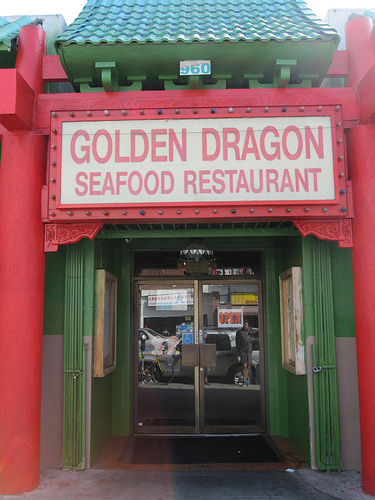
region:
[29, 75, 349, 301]
an Asian restaurant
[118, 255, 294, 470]
the entrance way to the restaurant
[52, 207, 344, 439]
the entrance way has green trim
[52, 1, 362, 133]
the top part of the eatery is green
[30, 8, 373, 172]
this roof has an Far Eastern design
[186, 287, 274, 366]
this restaurant is open for business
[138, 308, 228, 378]
this diner is handicap accessible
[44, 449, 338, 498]
the ground beneath the door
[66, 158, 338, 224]
this diner specializes in seafood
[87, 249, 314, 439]
there are two pictures at the entrance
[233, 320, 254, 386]
a reflection of a man standing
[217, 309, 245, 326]
a red and white open sign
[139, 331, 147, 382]
a black and gray parking meter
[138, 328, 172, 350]
part of a car in a window reflection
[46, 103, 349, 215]
a red and white restaurant sign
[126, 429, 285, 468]
a black door mat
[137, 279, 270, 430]
the doors of a restaurant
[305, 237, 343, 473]
part of a green door frame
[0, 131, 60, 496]
a large red pole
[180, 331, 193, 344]
a blue and white handicapped sign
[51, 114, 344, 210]
sign for the restaurant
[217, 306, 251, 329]
sign indicating they are open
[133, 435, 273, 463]
mat to wipe your feet on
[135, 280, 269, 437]
doors for the restaurant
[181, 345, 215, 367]
things to pull open the doors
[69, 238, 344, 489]
gates they close when restaurant closes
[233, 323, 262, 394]
man's reflection taking picture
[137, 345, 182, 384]
reflection of man's bike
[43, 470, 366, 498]
side walk leading to restaurant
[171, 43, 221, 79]
address of restaurant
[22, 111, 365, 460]
The Golden Dragon seafood restaurant entry way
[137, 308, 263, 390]
Reflection of the people and cars across from the restaurant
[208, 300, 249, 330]
Sign indicating the restaurant is open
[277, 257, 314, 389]
Enclosed bulletin boards displaying information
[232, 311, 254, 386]
Man standing across from the restaurant looking at it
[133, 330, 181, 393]
A bicycle attached to a parking meter across from the restaurant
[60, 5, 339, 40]
Traditional Eastern-style clay tiles painted green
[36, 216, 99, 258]
Traditional Eastern ornamentation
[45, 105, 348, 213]
Light bulbs surrounding sign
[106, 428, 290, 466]
Large doormat in front of door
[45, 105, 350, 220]
The Golden Dragon Seafood Restaurant sign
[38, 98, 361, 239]
The sign is red and white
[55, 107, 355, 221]
the lights around the sign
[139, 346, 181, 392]
the reflection of the bicycle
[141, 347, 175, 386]
the bicycle is orange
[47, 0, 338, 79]
the awning above the sign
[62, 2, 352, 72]
the awning is green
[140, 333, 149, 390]
the parking meter beside the bicycle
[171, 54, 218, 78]
the number 960 below the awning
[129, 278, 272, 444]
the doors are closed